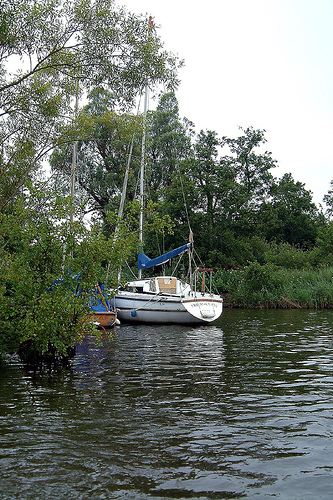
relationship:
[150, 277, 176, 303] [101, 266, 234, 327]
trim on boat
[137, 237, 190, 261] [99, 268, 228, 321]
pole on boat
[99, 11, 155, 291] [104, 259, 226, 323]
poles are on boat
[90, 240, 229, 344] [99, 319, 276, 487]
boat in water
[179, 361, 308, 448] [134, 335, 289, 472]
light hitting water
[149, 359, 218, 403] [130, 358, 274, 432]
ripples in water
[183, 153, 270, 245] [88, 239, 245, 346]
trees near boat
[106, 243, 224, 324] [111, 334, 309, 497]
boat in water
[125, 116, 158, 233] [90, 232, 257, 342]
pole on boat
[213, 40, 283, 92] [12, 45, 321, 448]
sky above land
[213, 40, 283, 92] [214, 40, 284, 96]
sky with no clouds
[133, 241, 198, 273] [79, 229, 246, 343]
part of boat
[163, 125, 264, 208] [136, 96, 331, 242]
branches on tree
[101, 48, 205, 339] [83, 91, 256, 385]
poles for sails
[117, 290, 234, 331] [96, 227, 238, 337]
trim on boat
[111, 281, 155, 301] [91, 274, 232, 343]
window on boat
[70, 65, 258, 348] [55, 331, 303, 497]
boat in a river